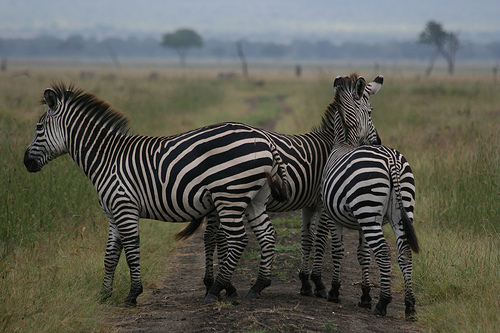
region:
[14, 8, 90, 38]
white clouds in blue sky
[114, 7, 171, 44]
white clouds in blue sky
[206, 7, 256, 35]
white clouds in blue sky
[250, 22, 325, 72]
white clouds in blue sky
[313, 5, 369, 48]
white clouds in blue sky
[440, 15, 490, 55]
white clouds in blue sky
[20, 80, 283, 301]
black and white zebra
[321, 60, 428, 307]
black and white zebra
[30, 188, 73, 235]
green and brown grass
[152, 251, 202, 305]
green and brown grass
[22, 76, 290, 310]
A black and white zebra.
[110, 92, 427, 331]
A dirt road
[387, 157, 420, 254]
A zebra tail.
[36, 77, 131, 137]
A mane on a zebra head.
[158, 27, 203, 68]
A tree in the distance.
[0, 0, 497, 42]
A blue sky in the distance.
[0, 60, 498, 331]
Yellow and green grass.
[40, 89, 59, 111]
A zebra's ear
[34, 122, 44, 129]
The left eye of a zebra.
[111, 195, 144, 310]
Front leg of a zebra.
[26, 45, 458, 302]
three zebras standing together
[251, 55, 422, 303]
two zebras leaning on each other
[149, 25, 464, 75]
two trees on horizon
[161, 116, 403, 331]
path zebras are walking on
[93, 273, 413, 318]
black feet of zebras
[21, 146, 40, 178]
black nose of zebra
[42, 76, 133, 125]
black and white mane of zebra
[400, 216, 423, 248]
black tail of zebra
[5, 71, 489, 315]
grass surrounding dirt path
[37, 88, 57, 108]
black ear of zebra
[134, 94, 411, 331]
A dirt path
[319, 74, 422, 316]
A zebra on a dirt path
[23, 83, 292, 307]
A zebra on a dirt path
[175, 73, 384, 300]
A zebra on a dirt path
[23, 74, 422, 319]
A trio of zebras on a dirt path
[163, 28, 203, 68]
A tall, full tree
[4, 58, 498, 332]
A grassy landscape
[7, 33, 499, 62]
A large forested area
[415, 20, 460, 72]
A tall tree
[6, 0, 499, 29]
A cloudy sky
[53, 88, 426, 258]
Three zebra is standing in road.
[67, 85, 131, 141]
Short hairs on back of zebra.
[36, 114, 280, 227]
Zebra is black and white color.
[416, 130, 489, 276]
Grass are green and brown color.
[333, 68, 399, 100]
Two pointed ears for zebra.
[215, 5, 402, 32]
Sky is blue color.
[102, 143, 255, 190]
Stripe design in zebra.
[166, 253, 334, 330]
Road is grey color.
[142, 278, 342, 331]
Dried grass on road.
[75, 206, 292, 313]
Four legs for zebra.